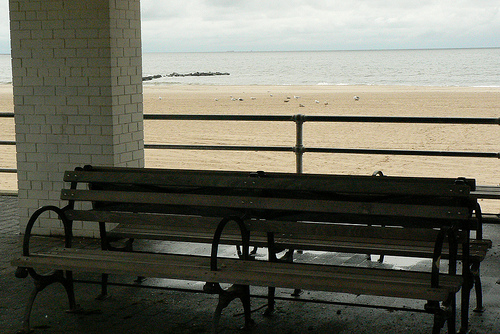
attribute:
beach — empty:
[6, 157, 492, 332]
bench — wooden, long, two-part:
[16, 164, 490, 331]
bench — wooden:
[43, 167, 463, 309]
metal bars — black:
[22, 203, 72, 255]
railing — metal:
[145, 112, 498, 123]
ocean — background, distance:
[0, 48, 498, 86]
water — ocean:
[18, 35, 455, 91]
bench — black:
[81, 154, 496, 329]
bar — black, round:
[197, 215, 257, 327]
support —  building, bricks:
[12, 67, 123, 155]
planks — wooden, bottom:
[15, 242, 466, 299]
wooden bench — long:
[32, 152, 484, 306]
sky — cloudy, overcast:
[251, 15, 386, 42]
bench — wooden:
[11, 144, 497, 325]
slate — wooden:
[58, 184, 490, 223]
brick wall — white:
[9, 0, 146, 238]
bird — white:
[309, 95, 324, 104]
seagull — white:
[353, 92, 359, 100]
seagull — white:
[324, 100, 329, 105]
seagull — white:
[313, 98, 319, 104]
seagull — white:
[298, 103, 305, 107]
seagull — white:
[293, 95, 300, 99]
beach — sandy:
[0, 47, 498, 215]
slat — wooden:
[58, 165, 480, 204]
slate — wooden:
[108, 179, 483, 264]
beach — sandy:
[0, 85, 499, 212]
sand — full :
[1, 85, 498, 213]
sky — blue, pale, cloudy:
[348, 0, 412, 20]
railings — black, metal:
[143, 110, 498, 182]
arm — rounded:
[405, 202, 483, 331]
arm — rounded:
[3, 183, 85, 273]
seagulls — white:
[217, 97, 372, 110]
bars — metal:
[146, 105, 498, 131]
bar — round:
[418, 225, 478, 332]